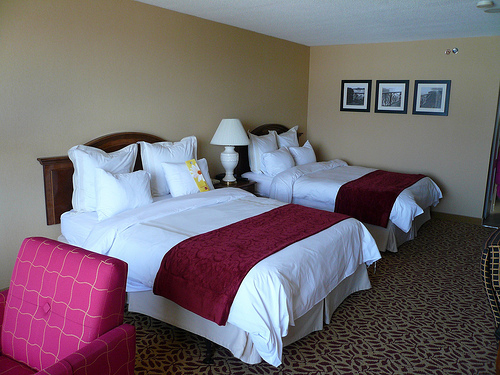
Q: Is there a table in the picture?
A: Yes, there is a table.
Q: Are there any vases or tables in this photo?
A: Yes, there is a table.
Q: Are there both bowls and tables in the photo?
A: No, there is a table but no bowls.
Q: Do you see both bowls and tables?
A: No, there is a table but no bowls.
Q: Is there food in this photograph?
A: No, there is no food.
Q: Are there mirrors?
A: No, there are no mirrors.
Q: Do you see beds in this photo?
A: Yes, there is a bed.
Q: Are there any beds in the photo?
A: Yes, there is a bed.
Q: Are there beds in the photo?
A: Yes, there is a bed.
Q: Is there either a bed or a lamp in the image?
A: Yes, there is a bed.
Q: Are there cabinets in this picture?
A: No, there are no cabinets.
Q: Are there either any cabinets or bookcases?
A: No, there are no cabinets or bookcases.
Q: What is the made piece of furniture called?
A: The piece of furniture is a bed.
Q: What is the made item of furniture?
A: The piece of furniture is a bed.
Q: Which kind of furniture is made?
A: The furniture is a bed.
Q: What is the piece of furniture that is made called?
A: The piece of furniture is a bed.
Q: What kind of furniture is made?
A: The furniture is a bed.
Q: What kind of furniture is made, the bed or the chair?
A: The bed is made.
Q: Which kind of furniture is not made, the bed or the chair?
A: The chair is not made.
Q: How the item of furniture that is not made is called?
A: The piece of furniture is a chair.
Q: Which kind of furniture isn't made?
A: The furniture is a chair.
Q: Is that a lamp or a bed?
A: That is a bed.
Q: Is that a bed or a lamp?
A: That is a bed.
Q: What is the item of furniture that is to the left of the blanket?
A: The piece of furniture is a bed.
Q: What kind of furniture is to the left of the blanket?
A: The piece of furniture is a bed.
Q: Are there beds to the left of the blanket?
A: Yes, there is a bed to the left of the blanket.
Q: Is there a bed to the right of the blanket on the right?
A: No, the bed is to the left of the blanket.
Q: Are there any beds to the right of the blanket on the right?
A: No, the bed is to the left of the blanket.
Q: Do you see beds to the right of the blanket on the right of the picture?
A: No, the bed is to the left of the blanket.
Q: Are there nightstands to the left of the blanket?
A: No, there is a bed to the left of the blanket.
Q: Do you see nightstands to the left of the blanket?
A: No, there is a bed to the left of the blanket.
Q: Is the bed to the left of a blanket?
A: Yes, the bed is to the left of a blanket.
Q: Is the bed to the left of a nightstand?
A: No, the bed is to the left of a blanket.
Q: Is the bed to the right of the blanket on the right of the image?
A: No, the bed is to the left of the blanket.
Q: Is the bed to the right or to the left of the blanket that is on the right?
A: The bed is to the left of the blanket.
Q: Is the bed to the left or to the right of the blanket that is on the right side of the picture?
A: The bed is to the left of the blanket.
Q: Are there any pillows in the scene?
A: Yes, there are pillows.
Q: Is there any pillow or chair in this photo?
A: Yes, there are pillows.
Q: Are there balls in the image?
A: No, there are no balls.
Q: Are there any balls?
A: No, there are no balls.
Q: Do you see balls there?
A: No, there are no balls.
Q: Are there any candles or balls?
A: No, there are no balls or candles.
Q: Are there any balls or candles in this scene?
A: No, there are no balls or candles.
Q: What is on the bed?
A: The pillows are on the bed.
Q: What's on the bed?
A: The pillows are on the bed.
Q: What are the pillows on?
A: The pillows are on the bed.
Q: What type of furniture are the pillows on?
A: The pillows are on the bed.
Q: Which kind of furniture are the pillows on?
A: The pillows are on the bed.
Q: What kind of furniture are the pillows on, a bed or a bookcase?
A: The pillows are on a bed.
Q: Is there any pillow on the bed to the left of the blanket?
A: Yes, there are pillows on the bed.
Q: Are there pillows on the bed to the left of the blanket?
A: Yes, there are pillows on the bed.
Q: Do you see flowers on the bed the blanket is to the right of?
A: No, there are pillows on the bed.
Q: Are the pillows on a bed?
A: Yes, the pillows are on a bed.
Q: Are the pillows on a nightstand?
A: No, the pillows are on a bed.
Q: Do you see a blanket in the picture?
A: Yes, there is a blanket.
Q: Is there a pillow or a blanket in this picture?
A: Yes, there is a blanket.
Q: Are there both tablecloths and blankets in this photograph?
A: No, there is a blanket but no tablecloths.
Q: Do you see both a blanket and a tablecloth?
A: No, there is a blanket but no tablecloths.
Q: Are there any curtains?
A: No, there are no curtains.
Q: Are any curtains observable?
A: No, there are no curtains.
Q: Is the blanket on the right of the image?
A: Yes, the blanket is on the right of the image.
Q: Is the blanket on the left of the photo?
A: No, the blanket is on the right of the image.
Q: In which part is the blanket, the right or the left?
A: The blanket is on the right of the image.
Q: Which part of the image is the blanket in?
A: The blanket is on the right of the image.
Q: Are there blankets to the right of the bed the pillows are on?
A: Yes, there is a blanket to the right of the bed.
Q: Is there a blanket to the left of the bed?
A: No, the blanket is to the right of the bed.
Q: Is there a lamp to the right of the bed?
A: No, there is a blanket to the right of the bed.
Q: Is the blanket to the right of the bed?
A: Yes, the blanket is to the right of the bed.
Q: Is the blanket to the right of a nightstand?
A: No, the blanket is to the right of the bed.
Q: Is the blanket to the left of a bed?
A: No, the blanket is to the right of a bed.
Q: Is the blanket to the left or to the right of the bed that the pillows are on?
A: The blanket is to the right of the bed.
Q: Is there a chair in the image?
A: Yes, there is a chair.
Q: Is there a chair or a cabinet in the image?
A: Yes, there is a chair.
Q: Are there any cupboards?
A: No, there are no cupboards.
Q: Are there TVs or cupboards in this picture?
A: No, there are no cupboards or tvs.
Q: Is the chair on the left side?
A: Yes, the chair is on the left of the image.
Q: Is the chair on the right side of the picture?
A: No, the chair is on the left of the image.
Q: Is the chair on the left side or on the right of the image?
A: The chair is on the left of the image.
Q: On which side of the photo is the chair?
A: The chair is on the left of the image.